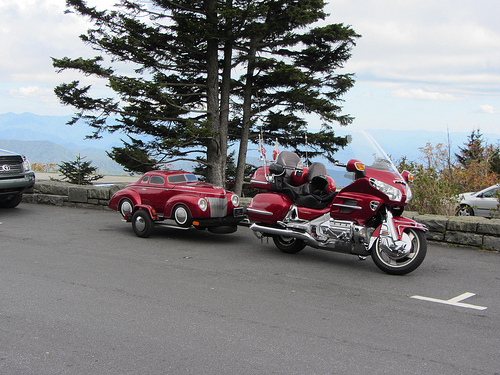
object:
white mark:
[408, 290, 488, 311]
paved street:
[0, 200, 499, 373]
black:
[0, 202, 498, 373]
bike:
[246, 141, 430, 277]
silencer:
[250, 223, 322, 244]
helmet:
[311, 175, 337, 198]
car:
[440, 179, 500, 220]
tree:
[48, 152, 105, 186]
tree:
[47, 0, 363, 188]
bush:
[55, 152, 105, 186]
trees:
[400, 127, 500, 218]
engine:
[309, 217, 364, 239]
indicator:
[354, 162, 365, 171]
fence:
[22, 179, 499, 252]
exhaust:
[249, 222, 314, 242]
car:
[107, 169, 248, 238]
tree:
[50, 1, 362, 200]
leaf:
[65, 117, 79, 126]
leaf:
[85, 134, 93, 141]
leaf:
[95, 54, 105, 61]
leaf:
[133, 67, 145, 73]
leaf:
[114, 117, 125, 123]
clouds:
[1, 1, 498, 133]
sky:
[1, 0, 500, 169]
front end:
[0, 149, 35, 209]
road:
[3, 195, 495, 373]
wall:
[12, 174, 496, 251]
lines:
[409, 291, 487, 311]